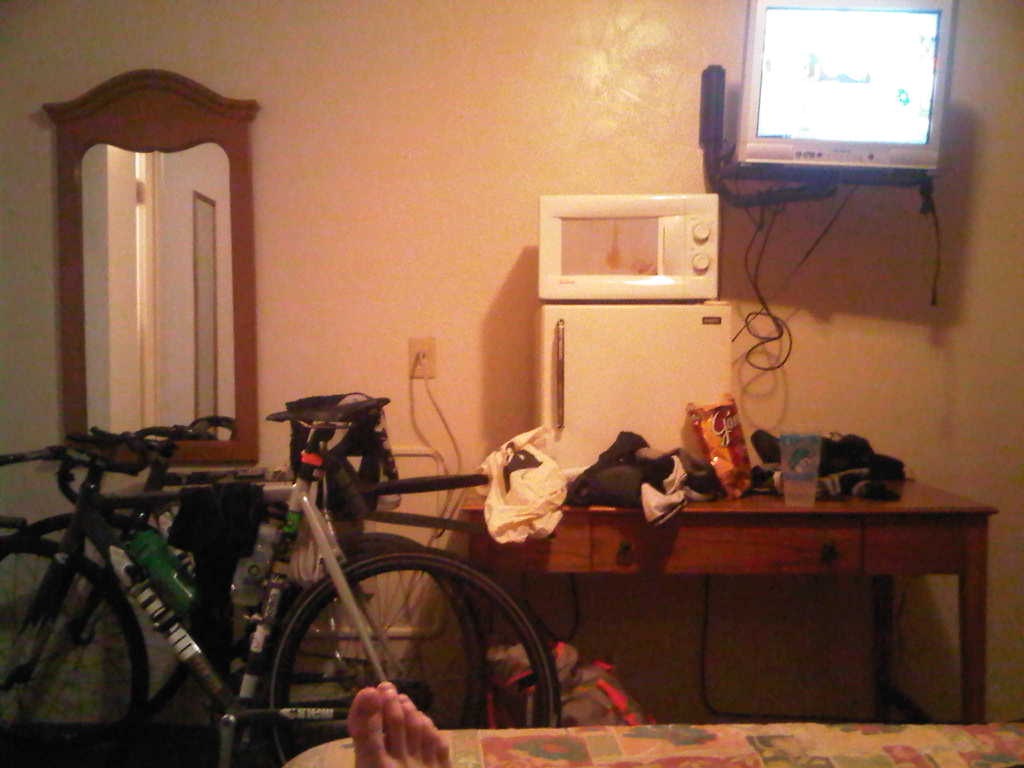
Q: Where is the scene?
A: In an apartment.